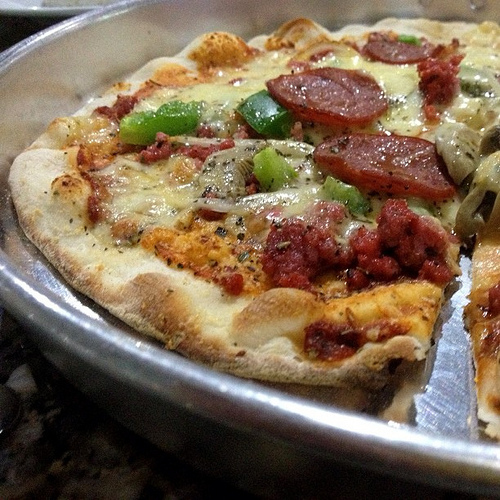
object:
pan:
[2, 1, 500, 498]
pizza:
[11, 20, 499, 423]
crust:
[9, 132, 403, 386]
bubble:
[229, 288, 322, 346]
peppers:
[118, 99, 205, 147]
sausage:
[311, 131, 455, 202]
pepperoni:
[266, 64, 389, 128]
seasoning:
[215, 215, 249, 262]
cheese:
[185, 60, 270, 103]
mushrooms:
[199, 148, 255, 199]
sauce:
[263, 197, 450, 287]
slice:
[470, 204, 500, 438]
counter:
[0, 272, 497, 500]